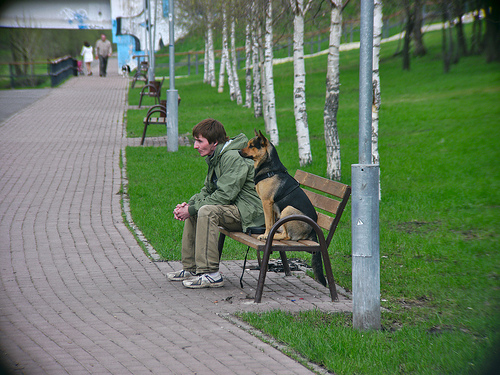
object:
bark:
[372, 81, 376, 108]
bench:
[140, 90, 181, 149]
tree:
[250, 0, 263, 119]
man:
[165, 113, 269, 289]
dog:
[237, 127, 328, 287]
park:
[2, 1, 499, 373]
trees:
[394, 3, 419, 72]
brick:
[230, 353, 252, 363]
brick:
[246, 360, 263, 367]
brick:
[251, 367, 272, 372]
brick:
[254, 353, 278, 361]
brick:
[159, 362, 187, 368]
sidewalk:
[0, 50, 332, 373]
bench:
[213, 169, 353, 301]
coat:
[186, 133, 277, 232]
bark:
[325, 106, 339, 130]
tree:
[324, 0, 341, 185]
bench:
[129, 58, 149, 87]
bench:
[135, 74, 163, 110]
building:
[108, 2, 170, 73]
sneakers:
[182, 270, 228, 288]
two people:
[78, 34, 112, 76]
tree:
[3, 14, 54, 87]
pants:
[179, 199, 242, 276]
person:
[79, 40, 93, 77]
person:
[94, 32, 114, 76]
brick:
[29, 249, 59, 274]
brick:
[274, 288, 297, 301]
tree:
[179, 50, 212, 78]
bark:
[326, 91, 339, 117]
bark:
[297, 103, 305, 116]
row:
[129, 55, 352, 301]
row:
[195, 31, 385, 196]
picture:
[6, 59, 492, 295]